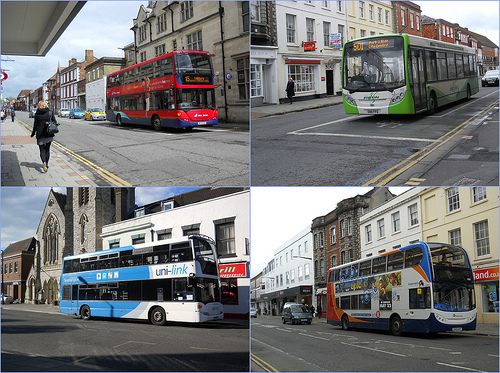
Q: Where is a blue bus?
A: Bottom left picture.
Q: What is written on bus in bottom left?
A: Uni-link.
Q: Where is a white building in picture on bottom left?
A: Behind bus.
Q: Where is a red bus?
A: Top left picture.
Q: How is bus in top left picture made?
A: Double decker.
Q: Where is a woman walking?
A: Sidewalk in picture on top left.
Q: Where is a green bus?
A: Top right picture.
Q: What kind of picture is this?
A: Collage.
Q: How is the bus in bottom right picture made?
A: Double decker.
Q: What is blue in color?
A: Side of the bus.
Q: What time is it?
A: Afternoon.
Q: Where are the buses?
A: On the street.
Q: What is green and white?
A: The bus.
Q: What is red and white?
A: The bus.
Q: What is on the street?
A: Lines.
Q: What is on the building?
A: Windows.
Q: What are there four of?
A: Pictures.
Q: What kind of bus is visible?
A: Blue bus.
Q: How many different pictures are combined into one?
A: Four.